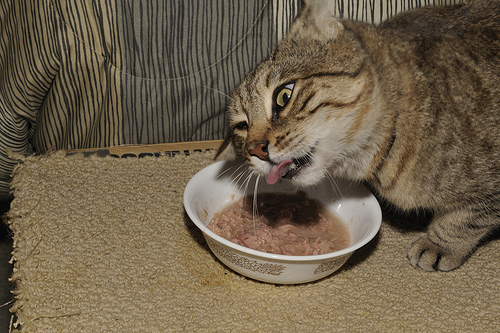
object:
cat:
[223, 0, 499, 270]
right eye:
[233, 120, 249, 133]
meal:
[182, 157, 383, 286]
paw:
[406, 233, 466, 271]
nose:
[247, 141, 271, 161]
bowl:
[183, 157, 383, 286]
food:
[200, 185, 351, 258]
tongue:
[267, 159, 293, 185]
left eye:
[271, 80, 297, 112]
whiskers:
[204, 155, 260, 236]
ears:
[303, 0, 333, 23]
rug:
[1, 145, 500, 332]